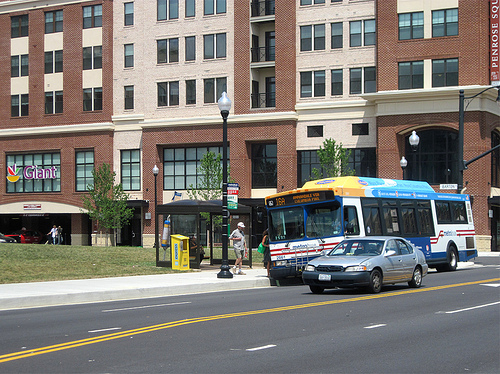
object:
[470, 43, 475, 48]
text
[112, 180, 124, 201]
green leaves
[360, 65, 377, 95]
windows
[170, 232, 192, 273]
stand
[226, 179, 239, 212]
bus sign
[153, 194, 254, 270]
bus stop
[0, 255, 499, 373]
street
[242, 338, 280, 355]
lines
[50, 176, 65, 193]
window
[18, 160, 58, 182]
giant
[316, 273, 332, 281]
license plate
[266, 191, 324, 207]
marquee display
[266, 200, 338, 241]
front windows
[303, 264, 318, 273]
headlights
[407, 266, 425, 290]
back tire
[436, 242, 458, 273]
back tire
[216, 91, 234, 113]
light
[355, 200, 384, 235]
passenger windows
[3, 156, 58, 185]
sign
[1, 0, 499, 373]
background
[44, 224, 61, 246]
people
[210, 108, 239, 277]
posts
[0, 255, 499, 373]
road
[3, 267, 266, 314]
side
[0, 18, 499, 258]
building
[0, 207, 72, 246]
entrance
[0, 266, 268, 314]
sidewalk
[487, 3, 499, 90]
sign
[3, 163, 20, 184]
logo